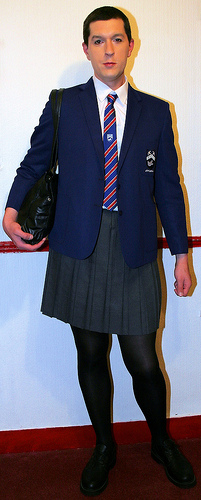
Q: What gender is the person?
A: Male.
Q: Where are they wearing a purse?
A: Right shoulder.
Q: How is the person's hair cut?
A: Buzz cut.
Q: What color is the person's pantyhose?
A: Black.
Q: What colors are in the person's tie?
A: Blue and red.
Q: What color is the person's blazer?
A: Navy blue.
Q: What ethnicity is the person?
A: White.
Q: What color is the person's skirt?
A: Grey.